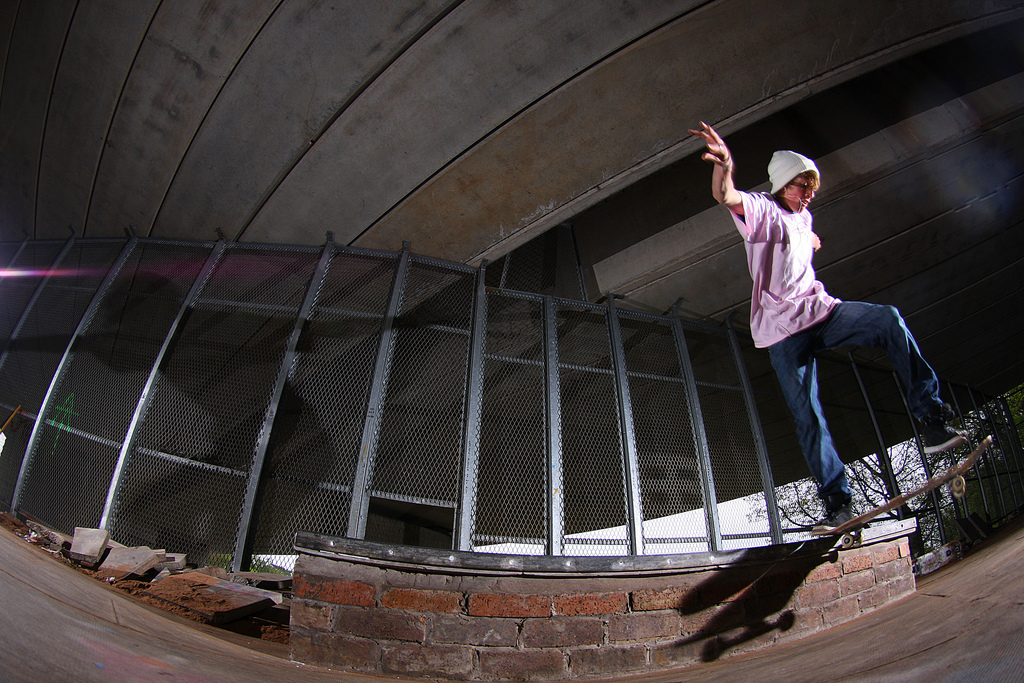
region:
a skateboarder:
[686, 117, 968, 526]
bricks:
[459, 588, 571, 671]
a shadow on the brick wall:
[676, 574, 791, 647]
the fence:
[484, 318, 712, 552]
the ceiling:
[436, 125, 561, 189]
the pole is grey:
[116, 408, 145, 470]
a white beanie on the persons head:
[766, 149, 804, 179]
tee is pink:
[721, 187, 849, 336]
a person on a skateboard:
[665, 89, 998, 565]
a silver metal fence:
[478, 298, 627, 555]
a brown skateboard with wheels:
[779, 426, 998, 578]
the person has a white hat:
[756, 140, 818, 194]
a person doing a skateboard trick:
[662, 95, 1007, 567]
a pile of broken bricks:
[61, 511, 295, 641]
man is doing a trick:
[602, 77, 1020, 660]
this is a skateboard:
[785, 417, 1004, 602]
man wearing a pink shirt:
[687, 168, 861, 361]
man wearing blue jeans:
[742, 266, 976, 495]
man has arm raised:
[670, 121, 784, 242]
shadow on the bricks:
[656, 493, 840, 680]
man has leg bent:
[789, 247, 985, 463]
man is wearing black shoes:
[771, 405, 999, 523]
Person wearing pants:
[770, 291, 958, 500]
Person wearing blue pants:
[763, 294, 945, 500]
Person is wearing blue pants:
[760, 288, 948, 504]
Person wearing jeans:
[756, 294, 940, 500]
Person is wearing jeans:
[750, 285, 932, 502]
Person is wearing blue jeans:
[760, 294, 932, 488]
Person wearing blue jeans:
[757, 292, 936, 496]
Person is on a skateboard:
[807, 419, 1010, 556]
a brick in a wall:
[286, 544, 404, 580]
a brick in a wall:
[291, 570, 383, 612]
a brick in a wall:
[371, 583, 466, 622]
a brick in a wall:
[466, 580, 553, 620]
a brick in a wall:
[555, 583, 633, 619]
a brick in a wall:
[640, 576, 718, 616]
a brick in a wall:
[708, 569, 789, 599]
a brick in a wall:
[283, 595, 331, 631]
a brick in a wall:
[332, 593, 424, 639]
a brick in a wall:
[425, 605, 521, 643]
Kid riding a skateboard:
[681, 109, 995, 550]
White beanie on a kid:
[747, 148, 827, 194]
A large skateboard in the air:
[813, 418, 998, 558]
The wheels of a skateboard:
[941, 469, 973, 501]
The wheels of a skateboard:
[832, 528, 861, 555]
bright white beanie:
[763, 148, 822, 194]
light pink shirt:
[719, 183, 841, 345]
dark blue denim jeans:
[742, 295, 968, 479]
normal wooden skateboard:
[794, 433, 1000, 551]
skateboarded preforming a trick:
[679, 115, 997, 552]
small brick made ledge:
[283, 519, 917, 668]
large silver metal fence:
[6, 221, 1013, 567]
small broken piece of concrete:
[65, 521, 113, 566]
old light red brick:
[473, 589, 554, 615]